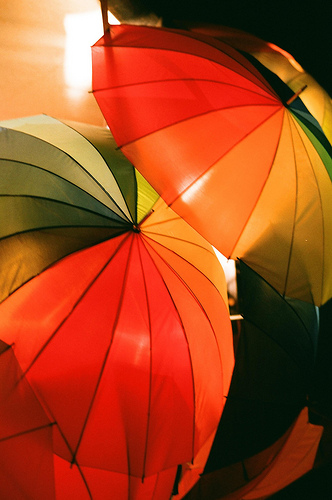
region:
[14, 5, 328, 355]
open umbrellas together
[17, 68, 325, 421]
open umbrellas grouped together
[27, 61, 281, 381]
orange and green umbrellas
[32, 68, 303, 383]
umbrellas that are different colors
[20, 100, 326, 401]
umbrella with different tones of orange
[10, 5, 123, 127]
a wooden floor with umbrellas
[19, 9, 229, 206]
umbrellas on a wooden floor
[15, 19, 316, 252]
umbrellas on a floor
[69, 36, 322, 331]
a lot of umbrellas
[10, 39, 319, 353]
the same open umbrellas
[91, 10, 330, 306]
a rainbow colored umbrella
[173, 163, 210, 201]
a bright light shining behind an orange panel on an umbrella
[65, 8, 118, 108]
a frosted bright light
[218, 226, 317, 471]
a green portion of an umbrella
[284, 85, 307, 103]
the top metal portion of an umbrella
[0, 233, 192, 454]
the red portion of an umbrella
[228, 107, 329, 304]
the yellow portion of an umbrella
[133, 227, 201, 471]
an umbrella spine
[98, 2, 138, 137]
a pole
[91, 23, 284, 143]
the red portion of a rainbow umbrella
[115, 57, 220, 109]
Red on the umbrella.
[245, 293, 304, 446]
The umbrella is black.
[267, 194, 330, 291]
Yellow on the umbrella.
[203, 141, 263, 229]
Orange on the umbrella.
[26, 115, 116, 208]
White on the umbrella.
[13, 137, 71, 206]
Grey on the umbrella.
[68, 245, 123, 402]
Wires on the umbrella.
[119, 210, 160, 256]
Connector on the umbrella.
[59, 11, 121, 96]
Light shining in the background.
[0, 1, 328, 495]
A group of umbrellas.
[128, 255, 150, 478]
panel of colorful umbrella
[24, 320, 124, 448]
panel of colorful umbrella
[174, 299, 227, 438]
panel of colorful umbrella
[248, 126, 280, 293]
panel of colorful umbrella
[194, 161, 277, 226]
panel of colorful umbrella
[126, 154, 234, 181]
panel of colorful umbrella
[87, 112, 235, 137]
panel of colorful umbrella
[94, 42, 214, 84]
panel of colorful umbrella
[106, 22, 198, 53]
panel of colorful umbrella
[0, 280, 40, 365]
panel of colorful umbrella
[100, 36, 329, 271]
a large colorful umbrella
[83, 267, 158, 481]
sticks inside the umbrella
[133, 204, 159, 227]
top part of the umbrella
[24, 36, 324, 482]
two set of umbrella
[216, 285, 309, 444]
a dark part of umbrella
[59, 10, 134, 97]
light shining on ground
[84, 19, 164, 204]
last part of the umbrella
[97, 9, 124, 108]
a small line in umbrella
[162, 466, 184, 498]
a black mark on umbrella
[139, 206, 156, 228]
a iron rod in middle